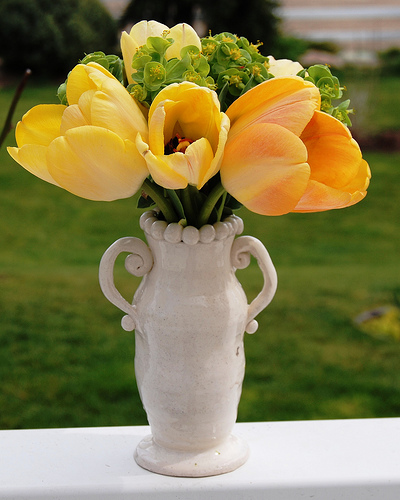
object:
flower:
[219, 75, 370, 217]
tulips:
[6, 19, 372, 217]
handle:
[98, 236, 153, 332]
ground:
[374, 178, 400, 206]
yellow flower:
[266, 55, 310, 79]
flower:
[135, 80, 230, 190]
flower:
[6, 61, 150, 202]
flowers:
[120, 19, 170, 84]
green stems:
[141, 178, 227, 227]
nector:
[98, 209, 277, 335]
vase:
[97, 209, 277, 478]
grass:
[0, 75, 399, 427]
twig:
[0, 68, 33, 149]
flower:
[161, 22, 201, 60]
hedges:
[0, 0, 60, 146]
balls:
[139, 208, 244, 245]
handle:
[230, 235, 278, 334]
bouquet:
[6, 19, 371, 226]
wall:
[274, 3, 400, 74]